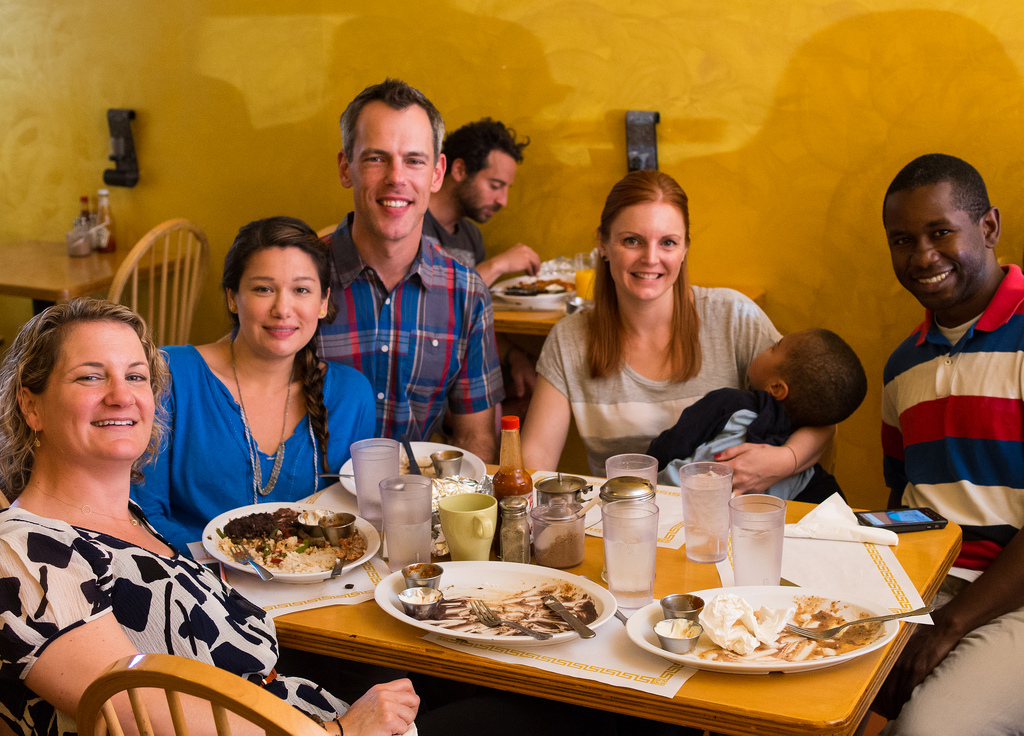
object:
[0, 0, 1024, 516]
wall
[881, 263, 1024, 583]
shirt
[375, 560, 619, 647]
plate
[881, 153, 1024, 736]
guy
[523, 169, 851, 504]
woman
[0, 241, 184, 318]
table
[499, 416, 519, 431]
lid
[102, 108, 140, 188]
accessory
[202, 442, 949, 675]
top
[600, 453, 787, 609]
cups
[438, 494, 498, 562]
yellow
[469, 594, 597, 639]
silver fork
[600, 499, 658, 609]
clear glass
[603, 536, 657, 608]
water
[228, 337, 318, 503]
silver necklace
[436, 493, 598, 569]
bunch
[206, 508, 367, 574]
rice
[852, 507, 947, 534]
black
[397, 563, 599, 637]
dirty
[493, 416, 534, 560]
hot sauce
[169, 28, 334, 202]
side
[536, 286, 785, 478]
black and white shir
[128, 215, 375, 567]
sitting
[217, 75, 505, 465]
man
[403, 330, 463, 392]
plaid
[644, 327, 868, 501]
child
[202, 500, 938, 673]
dinner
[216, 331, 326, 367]
neck